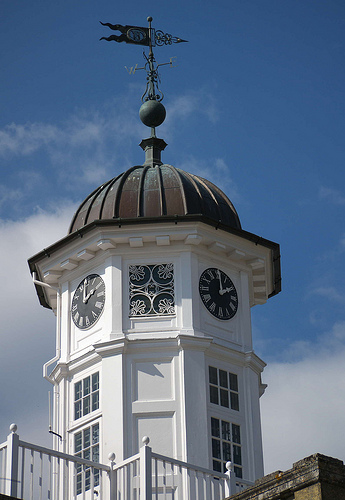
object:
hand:
[82, 278, 96, 304]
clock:
[70, 273, 105, 330]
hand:
[216, 271, 233, 295]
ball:
[142, 436, 150, 445]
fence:
[0, 424, 254, 500]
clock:
[199, 268, 238, 321]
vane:
[99, 21, 189, 75]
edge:
[234, 453, 345, 500]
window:
[75, 370, 99, 495]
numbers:
[74, 294, 79, 300]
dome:
[68, 163, 244, 235]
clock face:
[198, 265, 239, 319]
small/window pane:
[211, 417, 242, 485]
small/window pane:
[208, 365, 240, 411]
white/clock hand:
[83, 278, 96, 304]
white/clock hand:
[217, 271, 231, 295]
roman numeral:
[224, 276, 227, 283]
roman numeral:
[92, 277, 96, 286]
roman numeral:
[228, 285, 234, 291]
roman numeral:
[96, 281, 103, 290]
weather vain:
[98, 12, 190, 99]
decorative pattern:
[129, 262, 174, 317]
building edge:
[253, 391, 264, 476]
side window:
[208, 364, 243, 488]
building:
[26, 143, 280, 499]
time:
[80, 277, 104, 303]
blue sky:
[0, 0, 345, 357]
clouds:
[0, 205, 345, 470]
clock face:
[68, 271, 106, 331]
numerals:
[72, 304, 91, 326]